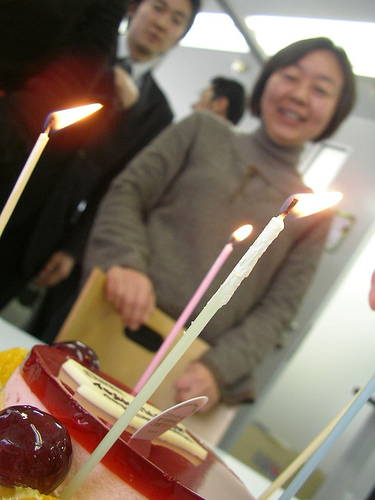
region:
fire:
[296, 194, 341, 217]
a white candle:
[199, 295, 232, 325]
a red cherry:
[2, 401, 63, 491]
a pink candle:
[192, 280, 208, 298]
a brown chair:
[83, 302, 116, 342]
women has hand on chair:
[112, 266, 166, 325]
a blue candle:
[312, 439, 337, 467]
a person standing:
[134, 4, 175, 73]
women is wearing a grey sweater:
[243, 289, 277, 339]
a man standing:
[198, 75, 234, 115]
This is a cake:
[22, 331, 191, 490]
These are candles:
[206, 203, 369, 336]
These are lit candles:
[261, 181, 373, 257]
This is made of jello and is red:
[32, 336, 213, 492]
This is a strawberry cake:
[29, 301, 232, 498]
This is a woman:
[160, 27, 368, 175]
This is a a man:
[38, 3, 183, 120]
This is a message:
[77, 364, 217, 459]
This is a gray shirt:
[151, 111, 361, 474]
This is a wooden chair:
[86, 276, 244, 437]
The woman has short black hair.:
[246, 26, 368, 153]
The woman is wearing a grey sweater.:
[68, 103, 331, 414]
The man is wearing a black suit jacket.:
[10, 34, 181, 264]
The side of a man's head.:
[183, 61, 243, 128]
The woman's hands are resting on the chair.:
[102, 262, 224, 412]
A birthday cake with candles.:
[3, 80, 372, 496]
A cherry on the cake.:
[0, 402, 72, 495]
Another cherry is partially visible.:
[49, 337, 97, 369]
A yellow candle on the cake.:
[65, 162, 348, 490]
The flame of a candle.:
[275, 176, 346, 223]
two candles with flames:
[32, 172, 343, 495]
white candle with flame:
[1, 70, 108, 255]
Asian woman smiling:
[68, 14, 358, 420]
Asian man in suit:
[0, 0, 212, 337]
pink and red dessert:
[1, 310, 273, 498]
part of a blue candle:
[282, 367, 373, 498]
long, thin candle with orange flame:
[33, 180, 343, 497]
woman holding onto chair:
[69, 11, 360, 422]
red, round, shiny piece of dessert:
[0, 384, 80, 499]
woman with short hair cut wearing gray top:
[78, 7, 342, 452]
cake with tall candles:
[13, 190, 343, 495]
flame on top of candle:
[259, 183, 349, 234]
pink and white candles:
[58, 189, 308, 493]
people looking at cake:
[91, 10, 363, 154]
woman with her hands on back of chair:
[64, 289, 250, 422]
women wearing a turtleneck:
[211, 112, 329, 196]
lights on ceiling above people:
[107, 10, 373, 59]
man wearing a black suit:
[11, 6, 191, 301]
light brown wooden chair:
[42, 277, 252, 432]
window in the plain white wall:
[287, 129, 360, 199]